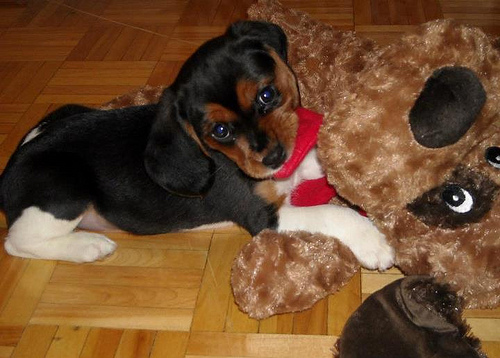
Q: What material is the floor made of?
A: Wood.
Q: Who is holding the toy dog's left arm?
A: The puppy.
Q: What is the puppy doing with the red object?
A: Chewing on it.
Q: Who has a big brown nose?
A: The stuffed animal.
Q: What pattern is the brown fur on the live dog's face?
A: A mask.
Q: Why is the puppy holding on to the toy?
A: To play.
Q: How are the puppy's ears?
A: Floppy.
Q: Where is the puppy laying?
A: On the wooden floor.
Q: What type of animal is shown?
A: Dog.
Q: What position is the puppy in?
A: Laying.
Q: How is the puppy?
A: Colorful.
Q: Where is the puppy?
A: Floor.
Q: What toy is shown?
A: Stuffed animal.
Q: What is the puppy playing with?
A: Stuffed animal.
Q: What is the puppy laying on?
A: Stuffed animal.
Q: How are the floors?
A: Hardwood.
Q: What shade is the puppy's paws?
A: White.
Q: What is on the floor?
A: Puppy.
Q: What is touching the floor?
A: Puppy ear.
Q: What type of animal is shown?
A: Puppy.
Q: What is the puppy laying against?
A: Plush dog.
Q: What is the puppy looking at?
A: Camera.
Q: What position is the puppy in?
A: Lying.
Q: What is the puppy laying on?
A: Floor.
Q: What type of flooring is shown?
A: Hardwood.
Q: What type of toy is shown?
A: Plush dog.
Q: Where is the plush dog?
A: In front of the puppy.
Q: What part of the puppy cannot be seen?
A: Back left leg.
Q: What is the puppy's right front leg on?
A: The toy.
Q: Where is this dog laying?
A: On the floor.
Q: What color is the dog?
A: Black, brown and white.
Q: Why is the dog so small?
A: He is a puppy.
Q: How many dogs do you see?
A: 1.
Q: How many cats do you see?
A: 0.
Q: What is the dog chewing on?
A: A stuffed animal.